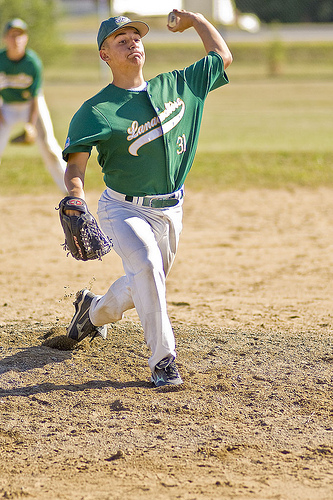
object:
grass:
[235, 138, 306, 172]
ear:
[99, 50, 110, 61]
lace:
[156, 357, 174, 373]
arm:
[189, 11, 233, 101]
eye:
[119, 39, 126, 43]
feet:
[150, 357, 182, 388]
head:
[97, 15, 146, 71]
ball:
[168, 11, 177, 27]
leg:
[101, 209, 173, 353]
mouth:
[127, 51, 143, 58]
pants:
[89, 185, 184, 371]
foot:
[66, 288, 95, 351]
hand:
[167, 8, 190, 33]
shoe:
[150, 356, 183, 387]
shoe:
[66, 289, 95, 342]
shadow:
[0, 332, 157, 395]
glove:
[54, 195, 114, 261]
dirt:
[0, 344, 82, 498]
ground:
[0, 25, 333, 500]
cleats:
[66, 289, 83, 335]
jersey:
[60, 51, 228, 198]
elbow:
[63, 168, 84, 180]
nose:
[129, 38, 140, 49]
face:
[109, 26, 145, 69]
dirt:
[183, 315, 333, 412]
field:
[0, 115, 333, 500]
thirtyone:
[177, 134, 186, 154]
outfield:
[0, 35, 333, 190]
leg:
[94, 225, 178, 326]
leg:
[25, 102, 66, 187]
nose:
[13, 38, 17, 46]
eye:
[135, 39, 141, 42]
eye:
[10, 35, 13, 38]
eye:
[16, 33, 20, 36]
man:
[54, 8, 234, 387]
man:
[0, 17, 68, 191]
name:
[126, 96, 185, 157]